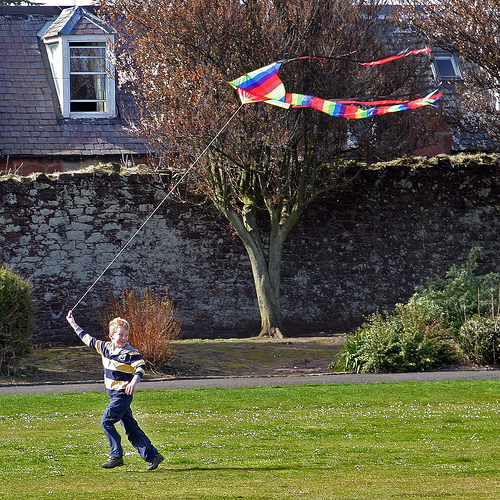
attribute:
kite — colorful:
[217, 45, 452, 119]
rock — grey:
[48, 215, 72, 227]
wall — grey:
[0, 153, 499, 337]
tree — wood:
[92, 0, 432, 342]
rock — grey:
[68, 189, 92, 210]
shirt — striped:
[74, 321, 147, 396]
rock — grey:
[63, 227, 85, 243]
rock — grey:
[74, 213, 97, 226]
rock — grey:
[93, 249, 116, 263]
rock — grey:
[67, 204, 83, 216]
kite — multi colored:
[218, 26, 441, 146]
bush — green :
[456, 310, 498, 367]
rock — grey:
[50, 215, 72, 224]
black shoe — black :
[100, 455, 124, 467]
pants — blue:
[82, 379, 167, 461]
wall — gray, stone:
[9, 179, 440, 299]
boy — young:
[64, 310, 164, 474]